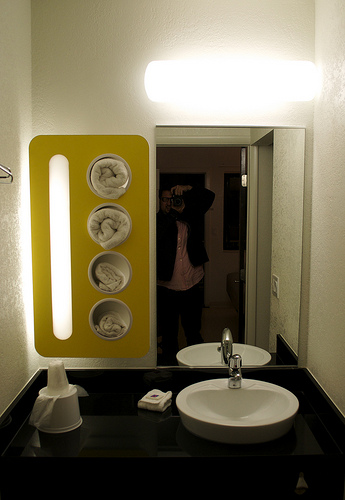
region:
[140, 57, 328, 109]
light over bathroom mirror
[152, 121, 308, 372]
bathroom mirror over sink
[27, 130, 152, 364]
yellow towel rack with light built in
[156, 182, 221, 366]
Mirror image of man taking a picture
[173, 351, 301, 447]
bathroom sink below mirror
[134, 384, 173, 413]
wash cloth with bar of soap on top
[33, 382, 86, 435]
Kleenex dispenser with plastic cups on top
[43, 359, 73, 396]
plastic cups on top of Kleenex dispenser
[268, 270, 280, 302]
mirror image of electrical socket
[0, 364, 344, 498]
black counter surrounding bathroom sink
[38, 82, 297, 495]
A person taking a picture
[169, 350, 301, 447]
The sink in the bathroom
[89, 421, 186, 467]
The counter in the bathroom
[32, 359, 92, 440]
The tissue dispenser in the bathroom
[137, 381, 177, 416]
The towel in the bathroom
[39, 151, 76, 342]
The lamp in the bathroom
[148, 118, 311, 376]
The mirror in the bathroom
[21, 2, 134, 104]
The color of the back wall is white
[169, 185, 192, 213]
The man has a black camera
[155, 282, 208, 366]
The man is wearing black pants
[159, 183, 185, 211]
Reflection of man holding a camera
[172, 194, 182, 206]
A camera in the hands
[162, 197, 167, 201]
A lens for eyeglasses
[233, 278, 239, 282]
Reflection of door handle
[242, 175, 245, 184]
Metallic reflection of door hinge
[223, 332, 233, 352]
Reflection of tap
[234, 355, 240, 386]
Hand basin metallic tap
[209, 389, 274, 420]
White hand basin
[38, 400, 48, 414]
White tissue paper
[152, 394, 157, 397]
Soap on folded towel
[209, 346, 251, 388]
faucet on the sink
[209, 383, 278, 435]
white sink under faucet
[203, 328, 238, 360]
faucet in the mirror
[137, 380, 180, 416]
cloth on the table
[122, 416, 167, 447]
black table next to sink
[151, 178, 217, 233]
man in the mirror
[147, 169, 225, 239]
man taking a photo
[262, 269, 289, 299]
light switch in mirror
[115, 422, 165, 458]
reflection on the counter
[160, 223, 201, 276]
shirt of the man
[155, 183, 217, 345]
Man taking a picture in the bathroom mirror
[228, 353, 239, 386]
Metal faucet on a sink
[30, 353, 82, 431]
Plastic cup dispenser in the bathroom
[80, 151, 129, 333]
Holes to hold towel in bathroom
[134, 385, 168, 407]
White washcloth with soap on it.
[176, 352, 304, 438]
White sink in bathroom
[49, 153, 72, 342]
Long tubular shaped bathroom light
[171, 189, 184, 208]
Camera being used to take a picture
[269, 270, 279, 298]
Light switch on bathroom wall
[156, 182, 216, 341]
Man wearing a pink button up shirt